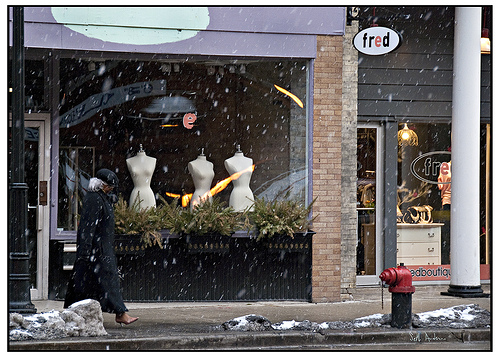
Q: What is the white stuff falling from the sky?
A: Snow.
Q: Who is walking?
A: A woman in a black coat.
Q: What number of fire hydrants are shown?
A: 1.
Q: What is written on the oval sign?
A: Fred.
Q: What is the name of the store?
A: Fred.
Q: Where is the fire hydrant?
A: Near the curb.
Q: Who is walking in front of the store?
A: A woman.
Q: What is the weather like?
A: It's snowing.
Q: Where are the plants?
A: In front of the store.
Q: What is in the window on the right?
A: A white dresser.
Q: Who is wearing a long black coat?
A: The woman in front of the store.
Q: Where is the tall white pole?
A: In front of the store.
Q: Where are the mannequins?
A: In the storefront window.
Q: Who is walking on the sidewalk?
A: A woman.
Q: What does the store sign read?
A: Fred.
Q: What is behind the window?
A: Three mannequins.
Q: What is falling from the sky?
A: Snow.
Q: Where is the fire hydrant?
A: On the sidewalk.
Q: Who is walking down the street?
A: A woman.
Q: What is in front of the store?
A: A white pole.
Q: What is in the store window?
A: Mannequins.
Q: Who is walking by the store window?
A: A woman.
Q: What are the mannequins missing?
A: Heads and arms.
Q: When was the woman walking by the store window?
A: Daytime.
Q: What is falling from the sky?
A: Snow.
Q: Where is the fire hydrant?
A: On the sidewalk.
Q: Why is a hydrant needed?
A: Water to put out fires.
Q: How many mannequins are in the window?
A: Three.